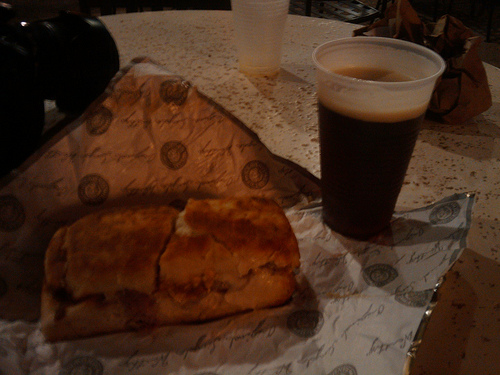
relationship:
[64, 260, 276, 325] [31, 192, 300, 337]
meat inside bread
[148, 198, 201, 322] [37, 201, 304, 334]
cut in middle of sandwich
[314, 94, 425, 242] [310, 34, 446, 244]
ale in cup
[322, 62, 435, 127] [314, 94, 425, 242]
head on ale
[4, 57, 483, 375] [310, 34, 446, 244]
paper under cup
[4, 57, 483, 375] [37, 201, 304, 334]
paper under sandwich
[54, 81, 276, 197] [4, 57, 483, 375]
design on paper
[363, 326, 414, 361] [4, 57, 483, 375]
words on paper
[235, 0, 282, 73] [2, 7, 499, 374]
cup on table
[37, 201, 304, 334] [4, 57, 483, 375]
sandwich on paper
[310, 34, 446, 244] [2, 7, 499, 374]
cup on table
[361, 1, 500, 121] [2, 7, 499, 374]
bag on table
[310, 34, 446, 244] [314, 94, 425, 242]
cup of ale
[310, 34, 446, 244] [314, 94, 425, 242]
cup has ale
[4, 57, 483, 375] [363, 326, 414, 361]
paper has words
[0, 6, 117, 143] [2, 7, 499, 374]
camera on table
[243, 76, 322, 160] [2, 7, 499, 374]
crumbs on table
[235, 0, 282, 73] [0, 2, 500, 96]
cup in background